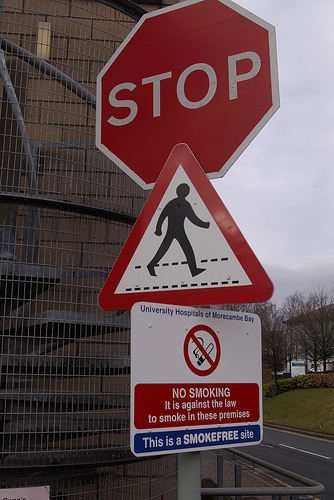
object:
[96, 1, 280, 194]
stop sign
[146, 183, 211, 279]
figure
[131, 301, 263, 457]
no smoking sign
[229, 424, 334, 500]
road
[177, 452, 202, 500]
sign post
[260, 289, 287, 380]
trees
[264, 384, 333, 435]
grass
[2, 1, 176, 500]
building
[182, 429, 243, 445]
smokefree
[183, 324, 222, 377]
no smoking picture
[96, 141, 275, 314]
sign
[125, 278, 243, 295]
dotted line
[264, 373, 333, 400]
bushes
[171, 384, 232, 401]
no smoking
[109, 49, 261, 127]
letters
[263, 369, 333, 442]
hill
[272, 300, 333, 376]
building